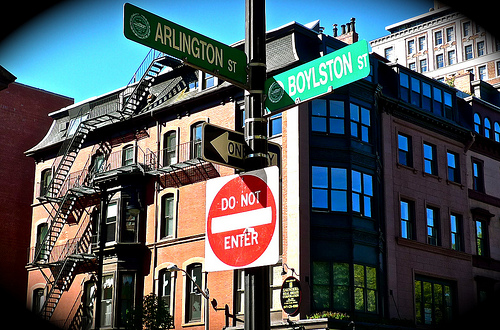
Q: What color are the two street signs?
A: Green.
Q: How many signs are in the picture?
A: Four.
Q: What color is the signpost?
A: Black.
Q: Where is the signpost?
A: At an intersection.